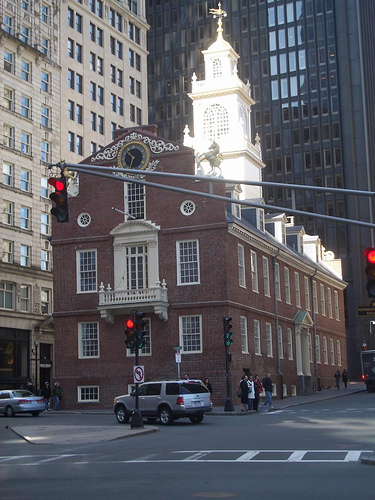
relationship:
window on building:
[251, 250, 257, 284] [49, 124, 349, 407]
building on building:
[146, 0, 374, 381] [49, 124, 349, 407]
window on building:
[20, 128, 31, 153] [1, 0, 148, 408]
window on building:
[271, 80, 280, 100] [146, 0, 374, 381]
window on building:
[277, 53, 287, 72] [146, 0, 374, 381]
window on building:
[127, 44, 141, 71] [1, 0, 148, 408]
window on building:
[170, 234, 206, 293] [41, 166, 354, 418]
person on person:
[237, 371, 248, 410] [261, 373, 274, 409]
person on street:
[246, 374, 255, 408] [1, 389, 374, 482]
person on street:
[253, 373, 262, 408] [1, 389, 374, 482]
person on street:
[261, 373, 274, 409] [1, 389, 374, 482]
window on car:
[166, 381, 208, 393] [121, 382, 212, 418]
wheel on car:
[111, 402, 131, 421] [106, 372, 222, 425]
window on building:
[74, 248, 104, 295] [51, 2, 348, 404]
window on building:
[120, 241, 153, 297] [51, 2, 348, 404]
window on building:
[242, 43, 347, 134] [146, 0, 374, 381]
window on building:
[76, 212, 89, 225] [49, 124, 349, 407]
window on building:
[180, 199, 195, 214] [49, 124, 349, 407]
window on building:
[77, 248, 98, 294] [49, 124, 349, 407]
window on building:
[122, 180, 144, 218] [49, 124, 349, 407]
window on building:
[176, 237, 201, 287] [49, 124, 349, 407]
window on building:
[237, 221, 285, 314] [51, 54, 311, 480]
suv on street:
[111, 377, 214, 426] [1, 390, 373, 498]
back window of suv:
[176, 382, 208, 393] [111, 377, 214, 426]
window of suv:
[134, 384, 162, 396] [107, 379, 210, 420]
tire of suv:
[156, 405, 174, 426] [111, 377, 214, 426]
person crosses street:
[259, 367, 273, 410] [281, 360, 374, 436]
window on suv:
[139, 384, 161, 395] [112, 377, 214, 426]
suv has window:
[112, 377, 214, 426] [133, 380, 165, 397]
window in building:
[172, 308, 209, 360] [49, 124, 349, 407]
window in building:
[123, 315, 154, 362] [49, 124, 349, 407]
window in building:
[78, 320, 100, 359] [58, 184, 323, 414]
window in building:
[76, 320, 99, 359] [49, 124, 349, 407]